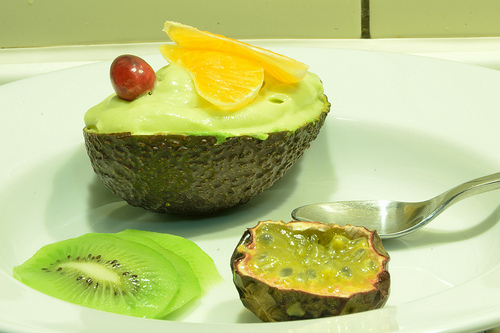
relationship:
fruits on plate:
[83, 61, 386, 306] [341, 43, 492, 329]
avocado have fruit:
[102, 92, 341, 192] [181, 20, 287, 95]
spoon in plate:
[313, 188, 485, 220] [341, 43, 492, 329]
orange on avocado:
[176, 30, 287, 100] [102, 92, 341, 192]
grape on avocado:
[101, 50, 158, 99] [102, 92, 341, 192]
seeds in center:
[270, 257, 369, 276] [269, 224, 377, 286]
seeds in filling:
[270, 257, 369, 276] [283, 274, 387, 302]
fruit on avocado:
[181, 20, 287, 95] [102, 92, 341, 192]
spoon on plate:
[313, 188, 485, 220] [341, 43, 492, 329]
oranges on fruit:
[181, 20, 287, 95] [102, 92, 341, 192]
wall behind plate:
[95, 1, 497, 46] [341, 43, 492, 329]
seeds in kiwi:
[63, 262, 132, 291] [46, 225, 213, 317]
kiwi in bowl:
[46, 225, 213, 317] [370, 57, 499, 275]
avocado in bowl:
[102, 92, 341, 192] [370, 57, 499, 275]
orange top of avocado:
[176, 30, 287, 100] [102, 92, 341, 192]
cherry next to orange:
[115, 61, 158, 91] [176, 30, 287, 100]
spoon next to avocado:
[313, 188, 485, 220] [102, 92, 341, 192]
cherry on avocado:
[115, 61, 158, 91] [102, 92, 341, 192]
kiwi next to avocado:
[46, 225, 213, 317] [102, 92, 341, 192]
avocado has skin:
[102, 92, 341, 192] [121, 139, 306, 193]